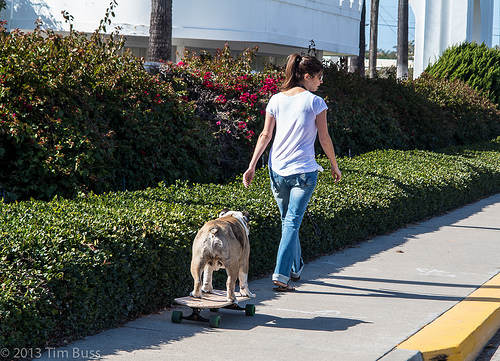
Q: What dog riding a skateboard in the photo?
A: Dog with woman.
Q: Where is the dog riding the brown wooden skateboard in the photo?
A: On the sidewalk.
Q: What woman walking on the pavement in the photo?
A: Woman wearing white shirt.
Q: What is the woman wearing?
A: A white shirt and jeans.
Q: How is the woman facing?
A: With her back to the camera.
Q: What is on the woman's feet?
A: Flip flops.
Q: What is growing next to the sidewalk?
A: Green shrubs.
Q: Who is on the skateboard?
A: A dog.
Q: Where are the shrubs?
A: To the left of the sidewalk.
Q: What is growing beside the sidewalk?
A: Green shrubs.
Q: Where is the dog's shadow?
A: On the sidewalk.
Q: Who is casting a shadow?
A: A dog and a woman.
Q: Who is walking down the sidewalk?
A: The woman.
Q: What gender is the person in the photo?
A: Female.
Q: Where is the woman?
A: On the sidewalk.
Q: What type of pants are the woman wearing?
A: Blue jeans.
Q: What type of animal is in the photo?
A: Dog.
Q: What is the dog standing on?
A: A skateboard.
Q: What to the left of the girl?
A: Bushes.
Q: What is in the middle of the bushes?
A: Flowers.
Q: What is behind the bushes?
A: Trees.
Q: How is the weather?
A: Sunny.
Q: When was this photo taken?
A: In the daytime.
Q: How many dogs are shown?
A: One.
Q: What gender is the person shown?
A: Female.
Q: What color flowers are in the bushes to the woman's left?
A: Pink.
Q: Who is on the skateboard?
A: Dog.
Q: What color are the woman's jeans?
A: Blue.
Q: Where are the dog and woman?
A: Sidewalk.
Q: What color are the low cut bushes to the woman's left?
A: Green.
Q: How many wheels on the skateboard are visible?
A: Four.